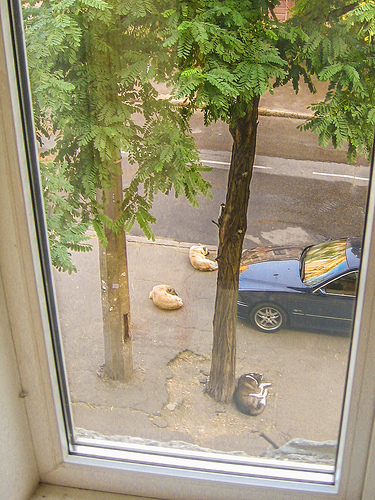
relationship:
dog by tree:
[186, 243, 225, 277] [20, 3, 371, 403]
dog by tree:
[144, 281, 190, 314] [20, 3, 371, 403]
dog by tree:
[234, 372, 272, 417] [20, 3, 371, 403]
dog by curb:
[188, 243, 218, 272] [133, 231, 222, 257]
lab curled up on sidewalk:
[145, 281, 186, 316] [47, 231, 341, 451]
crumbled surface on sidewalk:
[149, 358, 222, 429] [47, 231, 341, 451]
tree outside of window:
[184, 5, 373, 408] [5, 4, 370, 499]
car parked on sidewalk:
[234, 232, 363, 341] [124, 240, 186, 276]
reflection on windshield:
[308, 257, 323, 274] [300, 238, 354, 283]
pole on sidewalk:
[68, 16, 144, 380] [62, 200, 341, 463]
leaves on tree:
[19, 0, 373, 274] [169, 0, 323, 405]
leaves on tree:
[198, 75, 245, 105] [51, 3, 352, 411]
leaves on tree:
[332, 46, 360, 112] [295, 93, 368, 156]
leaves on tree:
[19, 0, 373, 274] [20, 3, 371, 403]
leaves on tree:
[41, 77, 92, 96] [20, 3, 371, 403]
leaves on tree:
[11, 0, 284, 152] [20, 3, 371, 403]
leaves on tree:
[154, 127, 185, 179] [121, 22, 183, 111]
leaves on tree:
[175, 24, 190, 60] [203, 31, 280, 406]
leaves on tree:
[246, 55, 274, 90] [203, 31, 280, 406]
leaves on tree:
[192, 162, 209, 193] [203, 31, 280, 406]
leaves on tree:
[309, 95, 342, 143] [203, 31, 280, 406]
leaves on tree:
[40, 9, 76, 55] [203, 31, 280, 406]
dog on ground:
[188, 243, 218, 272] [126, 229, 209, 415]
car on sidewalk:
[234, 232, 363, 341] [258, 332, 344, 360]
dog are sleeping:
[234, 372, 272, 417] [231, 373, 259, 422]